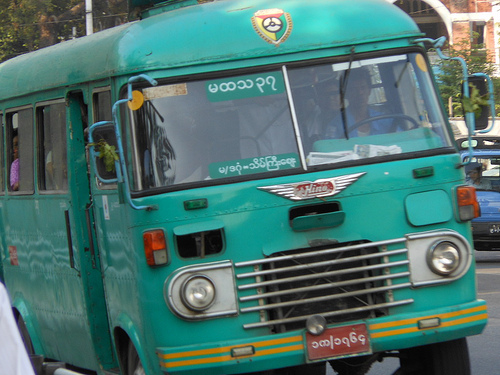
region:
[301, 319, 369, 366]
A red license plate on a truck.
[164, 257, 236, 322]
A right front headlight.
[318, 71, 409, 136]
A person driving a truck.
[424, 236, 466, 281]
A left front headlight.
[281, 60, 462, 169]
A front driver windshield.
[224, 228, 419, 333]
A metal grill on the front of a van.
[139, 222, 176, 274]
A right orange blinker.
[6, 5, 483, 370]
a big blue van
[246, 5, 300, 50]
a logo on the front of a automobile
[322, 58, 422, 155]
the driver of a vehicle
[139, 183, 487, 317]
the grill and headlights on a bus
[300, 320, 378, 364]
a license plate in another language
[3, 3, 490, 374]
a small blue bus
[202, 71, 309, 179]
foreign stickers on a wind shield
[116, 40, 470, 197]
the windshield of a vehicle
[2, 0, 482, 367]
a bus from an eastern country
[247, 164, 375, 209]
an emblem for a car company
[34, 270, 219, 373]
section of a bus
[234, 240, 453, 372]
section of a bus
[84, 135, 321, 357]
section of a bus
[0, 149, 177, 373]
section of a bus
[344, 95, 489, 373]
section of a bus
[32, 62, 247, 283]
section of a bus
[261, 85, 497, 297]
section of a bus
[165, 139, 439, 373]
section of a bus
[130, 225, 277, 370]
section of a bus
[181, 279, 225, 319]
round light on bus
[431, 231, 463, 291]
light on green bus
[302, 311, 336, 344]
light on green bus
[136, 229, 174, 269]
light on green bus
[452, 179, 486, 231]
light on green bus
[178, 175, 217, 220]
light on green bus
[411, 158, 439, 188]
light on green bus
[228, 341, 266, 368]
light on green bus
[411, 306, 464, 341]
light on green bus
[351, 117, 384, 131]
a steering wheel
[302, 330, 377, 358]
the license plate on the bus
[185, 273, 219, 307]
a clear headlight